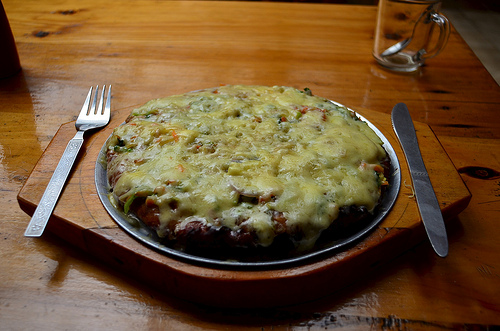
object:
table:
[0, 2, 499, 330]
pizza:
[103, 84, 393, 255]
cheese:
[103, 85, 392, 261]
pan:
[94, 98, 402, 273]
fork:
[24, 83, 111, 238]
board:
[17, 97, 469, 301]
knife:
[391, 101, 449, 255]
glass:
[373, 1, 447, 72]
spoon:
[381, 1, 437, 57]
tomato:
[145, 199, 157, 206]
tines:
[101, 86, 112, 115]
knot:
[59, 8, 79, 16]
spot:
[441, 106, 454, 111]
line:
[274, 310, 494, 329]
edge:
[402, 101, 482, 256]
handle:
[428, 14, 448, 52]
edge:
[95, 128, 118, 223]